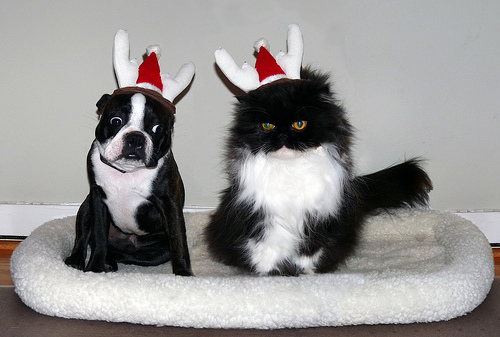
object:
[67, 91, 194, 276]
animal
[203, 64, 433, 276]
animal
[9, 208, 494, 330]
bed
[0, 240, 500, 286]
ground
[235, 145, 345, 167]
neck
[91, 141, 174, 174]
neck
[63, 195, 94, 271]
leg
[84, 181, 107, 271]
leg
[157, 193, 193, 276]
leg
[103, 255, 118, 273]
leg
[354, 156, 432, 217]
tail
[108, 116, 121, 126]
eye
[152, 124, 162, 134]
eye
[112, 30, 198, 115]
antlers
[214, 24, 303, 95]
antlers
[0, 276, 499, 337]
rug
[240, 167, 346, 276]
fur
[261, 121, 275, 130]
eye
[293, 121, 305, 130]
eye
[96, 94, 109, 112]
ear